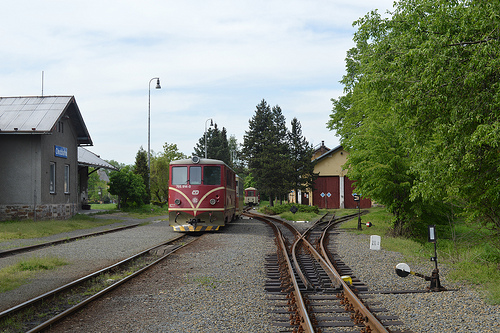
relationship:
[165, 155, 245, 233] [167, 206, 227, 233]
train has plow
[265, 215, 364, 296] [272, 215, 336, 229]
train track split apart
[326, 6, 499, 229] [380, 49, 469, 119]
trees have leaves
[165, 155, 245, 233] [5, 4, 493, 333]
train in summer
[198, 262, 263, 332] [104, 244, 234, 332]
gravel on ground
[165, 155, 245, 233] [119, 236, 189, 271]
train on tracks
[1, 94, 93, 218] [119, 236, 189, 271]
building near tracks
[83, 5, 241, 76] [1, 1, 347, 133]
clouds in sky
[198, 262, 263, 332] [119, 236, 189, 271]
gravel beside tracks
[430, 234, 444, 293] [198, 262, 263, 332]
junction box in gravel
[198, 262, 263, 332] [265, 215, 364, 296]
gravel near train track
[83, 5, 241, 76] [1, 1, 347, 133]
clouds are in sky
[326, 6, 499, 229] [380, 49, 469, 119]
tree has leaves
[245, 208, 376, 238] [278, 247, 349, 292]
three become one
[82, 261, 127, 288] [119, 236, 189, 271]
grass in tracks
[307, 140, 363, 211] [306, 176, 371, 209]
building has doors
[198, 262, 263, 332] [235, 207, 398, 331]
gravel on train track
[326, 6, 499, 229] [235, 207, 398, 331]
trees by train track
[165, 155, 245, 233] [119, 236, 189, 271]
train car on tracks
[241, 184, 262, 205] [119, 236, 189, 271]
train car on tracks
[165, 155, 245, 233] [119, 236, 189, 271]
train on railroad track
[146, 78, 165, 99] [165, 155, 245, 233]
lamp post above train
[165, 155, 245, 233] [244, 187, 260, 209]
train has train car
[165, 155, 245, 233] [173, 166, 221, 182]
train has window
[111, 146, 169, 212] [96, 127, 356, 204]
trees in background